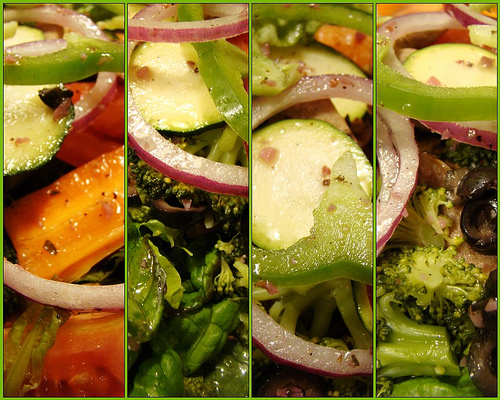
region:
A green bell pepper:
[378, 38, 498, 123]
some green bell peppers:
[252, 0, 370, 295]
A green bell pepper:
[175, 1, 245, 141]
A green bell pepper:
[2, 41, 122, 81]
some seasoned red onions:
[376, 1, 491, 246]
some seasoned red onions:
[250, 75, 365, 375]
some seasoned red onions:
[125, 5, 245, 196]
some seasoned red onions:
[1, 0, 121, 310]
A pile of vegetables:
[375, 2, 492, 392]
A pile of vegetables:
[251, 2, 373, 399]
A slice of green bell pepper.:
[0, 41, 126, 87]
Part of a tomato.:
[28, 309, 124, 396]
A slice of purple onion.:
[123, 93, 243, 194]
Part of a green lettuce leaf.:
[133, 311, 243, 396]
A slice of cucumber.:
[130, 40, 215, 132]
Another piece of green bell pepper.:
[251, 148, 369, 293]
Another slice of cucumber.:
[255, 115, 360, 250]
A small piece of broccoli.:
[377, 245, 488, 325]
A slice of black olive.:
[460, 185, 498, 257]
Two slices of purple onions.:
[374, 111, 426, 250]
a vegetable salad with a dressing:
[14, 3, 495, 398]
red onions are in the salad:
[128, 126, 247, 191]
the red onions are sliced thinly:
[377, 107, 494, 238]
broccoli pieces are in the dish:
[383, 190, 485, 391]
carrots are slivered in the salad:
[6, 157, 121, 279]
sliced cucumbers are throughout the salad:
[131, 39, 235, 129]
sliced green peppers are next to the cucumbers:
[261, 3, 497, 128]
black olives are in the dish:
[455, 168, 498, 258]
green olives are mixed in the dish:
[468, 340, 499, 390]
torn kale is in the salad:
[131, 235, 238, 373]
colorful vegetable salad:
[10, 17, 471, 368]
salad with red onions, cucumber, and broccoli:
[130, 68, 243, 278]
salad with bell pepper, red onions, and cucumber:
[11, 70, 113, 350]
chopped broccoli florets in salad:
[392, 230, 477, 380]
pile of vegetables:
[387, 43, 488, 358]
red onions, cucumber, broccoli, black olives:
[385, 23, 498, 288]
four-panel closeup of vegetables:
[10, 12, 494, 384]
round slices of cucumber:
[252, 52, 377, 329]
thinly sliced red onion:
[127, 59, 264, 242]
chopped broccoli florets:
[379, 201, 481, 398]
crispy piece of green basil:
[174, 328, 227, 363]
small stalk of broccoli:
[394, 309, 463, 378]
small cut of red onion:
[263, 331, 340, 373]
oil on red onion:
[313, 343, 372, 370]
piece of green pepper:
[302, 182, 377, 287]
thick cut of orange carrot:
[18, 176, 126, 257]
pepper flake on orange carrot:
[30, 228, 73, 260]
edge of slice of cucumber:
[16, 143, 78, 178]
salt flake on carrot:
[71, 165, 129, 213]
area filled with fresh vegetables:
[44, 31, 465, 338]